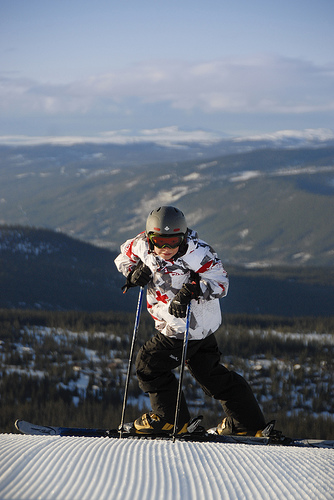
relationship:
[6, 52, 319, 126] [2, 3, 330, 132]
clouds in sky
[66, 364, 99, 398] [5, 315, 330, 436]
snow on ground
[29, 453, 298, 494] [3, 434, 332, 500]
lines on snow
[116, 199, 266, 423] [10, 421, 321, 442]
person on skis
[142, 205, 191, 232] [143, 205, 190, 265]
helmet on head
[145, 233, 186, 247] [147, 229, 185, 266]
goggles on face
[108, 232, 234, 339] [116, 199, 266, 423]
jacket on skier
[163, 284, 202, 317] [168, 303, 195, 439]
glove on pole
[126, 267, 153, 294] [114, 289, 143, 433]
glove on pole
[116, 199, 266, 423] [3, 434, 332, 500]
person at slope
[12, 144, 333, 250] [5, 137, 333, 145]
mountains on horizon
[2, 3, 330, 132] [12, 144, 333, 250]
sky above mountains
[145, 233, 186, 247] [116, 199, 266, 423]
goggles of skier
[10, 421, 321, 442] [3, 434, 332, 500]
skis in snow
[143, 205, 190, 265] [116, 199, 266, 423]
head of skier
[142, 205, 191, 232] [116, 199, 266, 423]
helmet on skier